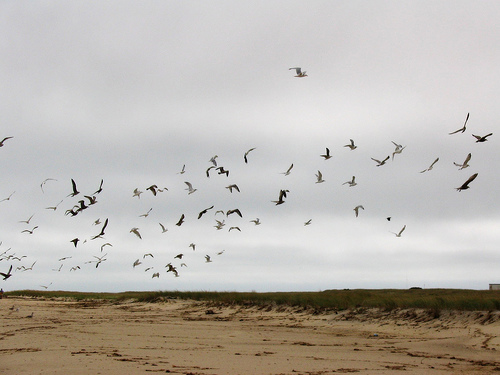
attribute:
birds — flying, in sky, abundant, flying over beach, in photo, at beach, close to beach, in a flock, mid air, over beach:
[67, 176, 307, 251]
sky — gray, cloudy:
[149, 21, 208, 46]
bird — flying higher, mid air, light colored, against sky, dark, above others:
[263, 48, 340, 94]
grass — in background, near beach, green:
[372, 284, 446, 317]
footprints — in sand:
[81, 346, 155, 371]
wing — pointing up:
[69, 175, 82, 192]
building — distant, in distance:
[485, 268, 499, 301]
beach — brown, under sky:
[149, 326, 269, 346]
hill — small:
[305, 281, 392, 326]